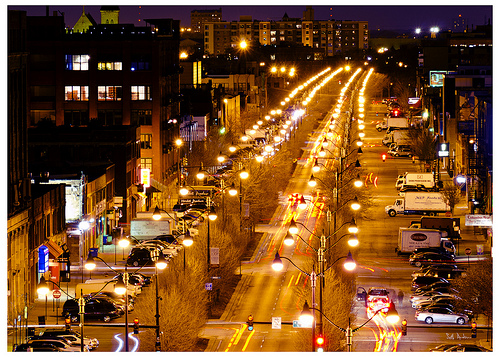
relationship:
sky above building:
[15, 5, 492, 43] [184, 14, 381, 65]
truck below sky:
[379, 187, 453, 216] [15, 5, 492, 43]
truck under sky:
[379, 187, 453, 216] [15, 5, 492, 43]